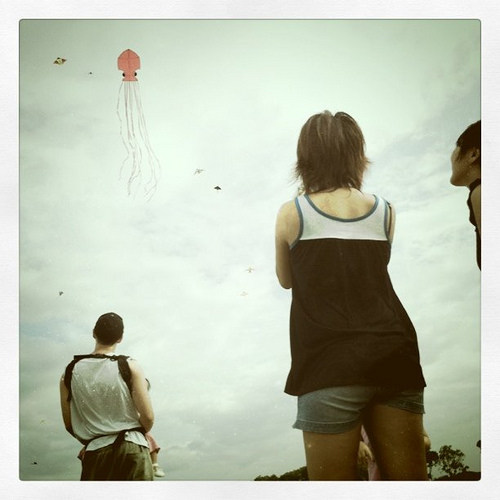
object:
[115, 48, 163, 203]
kite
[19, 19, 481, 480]
sky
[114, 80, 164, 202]
tail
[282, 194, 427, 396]
tank top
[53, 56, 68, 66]
kite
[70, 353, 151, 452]
tee shirt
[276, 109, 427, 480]
girl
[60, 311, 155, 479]
man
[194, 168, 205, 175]
kite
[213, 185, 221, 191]
kite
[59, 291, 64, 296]
kite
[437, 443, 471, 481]
tree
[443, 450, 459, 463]
leaves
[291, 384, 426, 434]
shorts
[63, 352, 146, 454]
baby carrier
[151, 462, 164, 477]
shoe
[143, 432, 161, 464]
leg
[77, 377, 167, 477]
baby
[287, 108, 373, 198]
hair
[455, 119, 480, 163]
hair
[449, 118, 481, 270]
girl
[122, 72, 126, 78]
eye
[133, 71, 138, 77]
eye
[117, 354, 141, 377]
shoulders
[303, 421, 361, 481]
leg